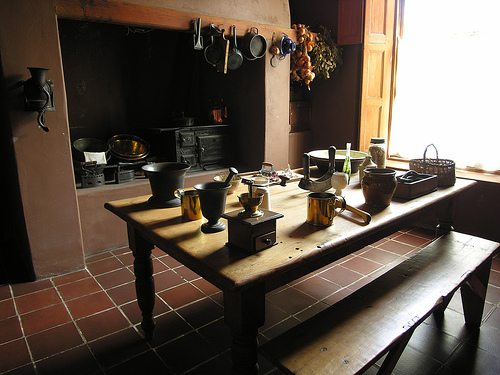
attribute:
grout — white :
[71, 320, 88, 345]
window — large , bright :
[374, 0, 498, 187]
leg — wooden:
[218, 287, 269, 370]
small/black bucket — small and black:
[138, 158, 192, 210]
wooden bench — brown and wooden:
[258, 230, 499, 374]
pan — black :
[192, 27, 316, 88]